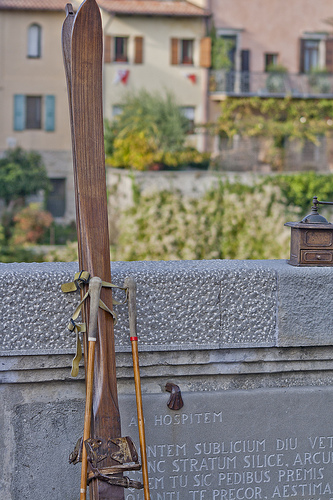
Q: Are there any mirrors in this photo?
A: No, there are no mirrors.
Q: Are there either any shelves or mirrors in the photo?
A: No, there are no mirrors or shelves.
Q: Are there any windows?
A: Yes, there is a window.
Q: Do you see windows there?
A: Yes, there is a window.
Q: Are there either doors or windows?
A: Yes, there is a window.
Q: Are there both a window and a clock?
A: No, there is a window but no clocks.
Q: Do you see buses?
A: No, there are no buses.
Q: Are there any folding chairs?
A: No, there are no folding chairs.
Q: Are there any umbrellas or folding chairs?
A: No, there are no folding chairs or umbrellas.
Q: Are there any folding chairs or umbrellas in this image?
A: No, there are no folding chairs or umbrellas.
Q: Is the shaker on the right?
A: Yes, the shaker is on the right of the image.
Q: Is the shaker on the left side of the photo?
A: No, the shaker is on the right of the image.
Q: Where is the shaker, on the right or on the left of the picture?
A: The shaker is on the right of the image.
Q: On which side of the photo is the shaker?
A: The shaker is on the right of the image.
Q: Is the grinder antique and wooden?
A: Yes, the grinder is antique and wooden.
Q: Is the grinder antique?
A: Yes, the grinder is antique.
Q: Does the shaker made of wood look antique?
A: Yes, the grinder is antique.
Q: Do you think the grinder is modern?
A: No, the grinder is antique.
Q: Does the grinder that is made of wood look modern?
A: No, the grinder is antique.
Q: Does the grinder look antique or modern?
A: The grinder is antique.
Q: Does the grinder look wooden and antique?
A: Yes, the grinder is wooden and antique.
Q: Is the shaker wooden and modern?
A: No, the shaker is wooden but antique.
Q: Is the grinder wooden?
A: Yes, the grinder is wooden.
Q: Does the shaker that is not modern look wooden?
A: Yes, the shaker is wooden.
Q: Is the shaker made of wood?
A: Yes, the shaker is made of wood.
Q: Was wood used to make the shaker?
A: Yes, the shaker is made of wood.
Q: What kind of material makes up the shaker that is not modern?
A: The shaker is made of wood.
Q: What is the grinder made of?
A: The shaker is made of wood.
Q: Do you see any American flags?
A: No, there are no American flags.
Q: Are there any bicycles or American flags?
A: No, there are no American flags or bicycles.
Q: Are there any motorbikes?
A: No, there are no motorbikes.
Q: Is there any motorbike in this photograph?
A: No, there are no motorcycles.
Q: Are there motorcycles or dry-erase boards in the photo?
A: No, there are no motorcycles or dry-erase boards.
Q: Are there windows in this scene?
A: Yes, there is a window.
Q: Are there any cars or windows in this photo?
A: Yes, there is a window.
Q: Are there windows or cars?
A: Yes, there is a window.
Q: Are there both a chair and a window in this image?
A: No, there is a window but no chairs.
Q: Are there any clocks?
A: No, there are no clocks.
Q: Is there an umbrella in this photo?
A: No, there are no umbrellas.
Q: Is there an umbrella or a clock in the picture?
A: No, there are no umbrellas or clocks.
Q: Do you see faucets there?
A: No, there are no faucets.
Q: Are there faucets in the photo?
A: No, there are no faucets.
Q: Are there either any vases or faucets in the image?
A: No, there are no faucets or vases.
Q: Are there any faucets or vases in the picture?
A: No, there are no faucets or vases.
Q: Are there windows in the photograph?
A: Yes, there is a window.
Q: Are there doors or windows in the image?
A: Yes, there is a window.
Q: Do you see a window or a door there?
A: Yes, there is a window.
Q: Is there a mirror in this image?
A: No, there are no mirrors.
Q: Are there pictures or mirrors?
A: No, there are no mirrors or pictures.